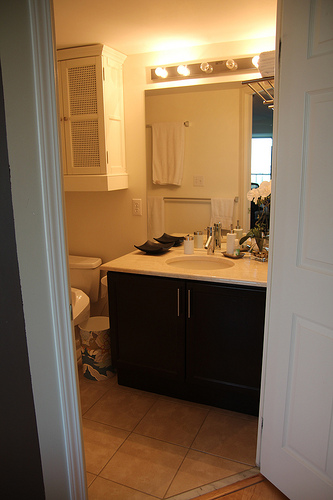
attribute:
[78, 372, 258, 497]
floor — tiled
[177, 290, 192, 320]
handles — metal, long, silver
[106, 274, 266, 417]
cabinet — black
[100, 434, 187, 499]
tile — tan, large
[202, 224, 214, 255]
faucet — silver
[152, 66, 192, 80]
lights — bright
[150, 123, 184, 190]
towel — hanging, white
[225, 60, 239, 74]
light bulb — clear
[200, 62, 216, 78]
light bulb — clear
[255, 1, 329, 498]
doorframe — white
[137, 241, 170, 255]
dish — black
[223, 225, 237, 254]
dispenser — white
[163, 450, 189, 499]
groutline — small, brown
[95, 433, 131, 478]
groutline — brown